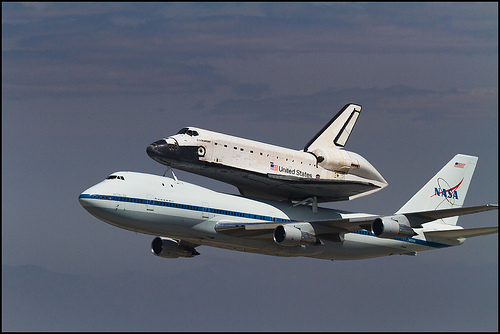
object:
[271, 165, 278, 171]
american flag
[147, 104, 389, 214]
space shuttle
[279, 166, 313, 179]
united states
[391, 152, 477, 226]
tail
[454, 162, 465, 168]
flag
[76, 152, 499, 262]
jet